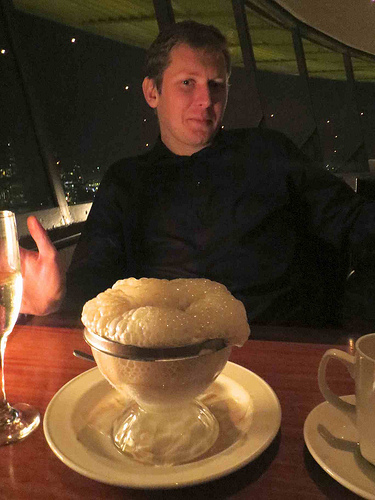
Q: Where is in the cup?
A: On the table.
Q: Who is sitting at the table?
A: A man.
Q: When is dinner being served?
A: At night.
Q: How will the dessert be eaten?
A: With a spoon.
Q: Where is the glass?
A: On the table.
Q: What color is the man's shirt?
A: Black.